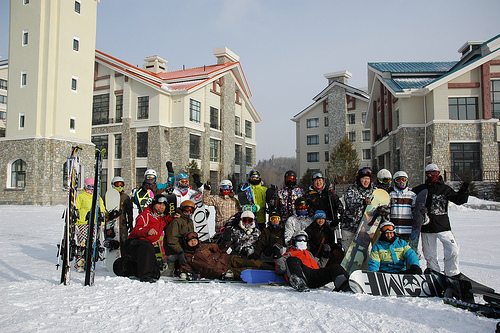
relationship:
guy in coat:
[365, 221, 423, 275] [365, 234, 422, 272]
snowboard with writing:
[347, 267, 464, 299] [363, 270, 439, 294]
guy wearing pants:
[410, 163, 473, 280] [415, 231, 463, 287]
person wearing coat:
[66, 174, 109, 273] [69, 189, 107, 227]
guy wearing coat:
[113, 194, 181, 282] [130, 207, 168, 245]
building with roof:
[0, 36, 265, 206] [129, 75, 201, 95]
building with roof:
[290, 34, 483, 187] [363, 32, 498, 92]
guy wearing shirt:
[393, 171, 417, 244] [365, 180, 426, 244]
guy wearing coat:
[365, 218, 427, 275] [367, 237, 420, 273]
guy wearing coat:
[113, 192, 168, 281] [127, 205, 175, 247]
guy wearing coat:
[176, 237, 265, 281] [177, 244, 231, 278]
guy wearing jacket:
[412, 162, 470, 275] [414, 182, 465, 230]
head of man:
[146, 195, 167, 213] [131, 192, 172, 278]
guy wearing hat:
[113, 194, 181, 282] [151, 194, 167, 209]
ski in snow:
[64, 150, 110, 290] [162, 304, 216, 329]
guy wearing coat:
[181, 231, 287, 282] [194, 247, 221, 274]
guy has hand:
[113, 194, 181, 282] [146, 230, 158, 236]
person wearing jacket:
[68, 178, 106, 272] [65, 170, 139, 240]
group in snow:
[72, 164, 472, 294] [3, 193, 498, 331]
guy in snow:
[410, 163, 473, 280] [3, 193, 498, 331]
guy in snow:
[389, 170, 417, 240] [3, 193, 498, 331]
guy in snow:
[365, 221, 423, 275] [3, 193, 498, 331]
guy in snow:
[113, 194, 181, 282] [3, 193, 498, 331]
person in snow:
[304, 173, 344, 225] [3, 193, 498, 331]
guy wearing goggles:
[389, 170, 417, 240] [393, 175, 408, 183]